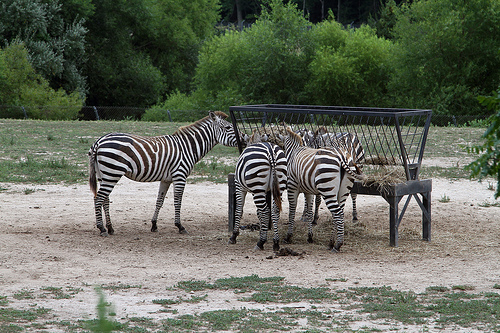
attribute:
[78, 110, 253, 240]
zebra — eating, in herd, the species, black, white, in group of four, striped, feeding, in group, feasting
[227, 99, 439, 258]
trough — black, for feeding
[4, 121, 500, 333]
ground — patchy, dirt, sandy, green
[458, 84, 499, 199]
leaves — green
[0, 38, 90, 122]
tree — green, in background, leafy, large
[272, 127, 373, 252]
zebra — standing, on the right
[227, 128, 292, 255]
zebra — in the middle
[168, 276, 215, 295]
grass — green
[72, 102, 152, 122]
fence — boarding pen